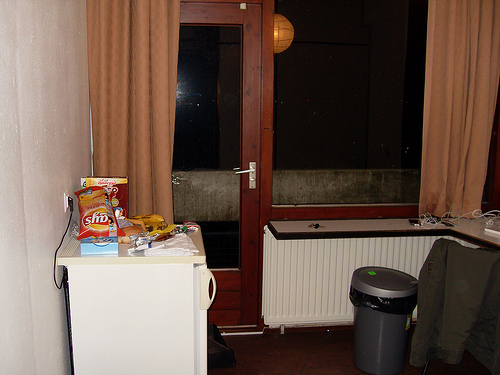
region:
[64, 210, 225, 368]
the mini fridge in the room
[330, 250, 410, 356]
the gray waste bin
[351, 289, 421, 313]
the black plastic bag in the waste bin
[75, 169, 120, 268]
the potato chips on the mini fridge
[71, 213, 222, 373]
the mini fridge is white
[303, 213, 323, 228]
the keys on the radiator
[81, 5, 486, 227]
the curtains are opened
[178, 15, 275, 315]
the door is closed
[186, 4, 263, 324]
the door is wood and glass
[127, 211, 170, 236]
the banana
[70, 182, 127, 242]
orange and red bag of chips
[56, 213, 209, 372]
small white mini fridge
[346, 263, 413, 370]
grey plastic trash can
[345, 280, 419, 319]
black bag in trash can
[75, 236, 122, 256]
small blue box on fridge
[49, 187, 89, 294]
black power cord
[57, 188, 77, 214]
black power cord plugged into outlet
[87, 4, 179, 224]
long brown curtain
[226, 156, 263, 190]
silver metal door handle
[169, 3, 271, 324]
door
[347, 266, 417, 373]
A grey trash can.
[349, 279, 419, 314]
A black trashbag.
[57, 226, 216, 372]
A white mini-fridge.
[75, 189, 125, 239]
An orange and yellow bag of chips.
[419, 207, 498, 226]
A long white cord.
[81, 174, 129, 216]
A box of cereal.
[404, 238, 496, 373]
A grey colored coat.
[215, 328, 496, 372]
Dark wooden floors.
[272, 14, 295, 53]
A round outside light.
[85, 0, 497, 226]
Beige curtains.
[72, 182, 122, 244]
this is a bag of chips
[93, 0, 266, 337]
this is a door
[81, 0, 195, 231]
this is a curtain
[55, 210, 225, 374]
this is a mini fridge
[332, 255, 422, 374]
this is a trash can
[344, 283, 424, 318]
this is a trash bag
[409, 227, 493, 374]
this is a jacket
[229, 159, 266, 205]
this is a door handle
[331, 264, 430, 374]
the trash can is grey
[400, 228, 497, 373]
the jacket is grey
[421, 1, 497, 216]
curtain on the right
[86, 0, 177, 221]
curtain on left by the door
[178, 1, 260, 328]
wood door with glass insert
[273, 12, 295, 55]
lit globe shaped ceiling light by the door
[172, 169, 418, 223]
wall on other side of the door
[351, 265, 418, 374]
dark round trash can with black plastic liner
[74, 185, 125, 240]
red bag of chips on white piece of furniture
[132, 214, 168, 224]
a banana to the right of red chips bag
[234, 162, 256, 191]
silver colored door handle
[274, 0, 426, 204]
window to the right of the door